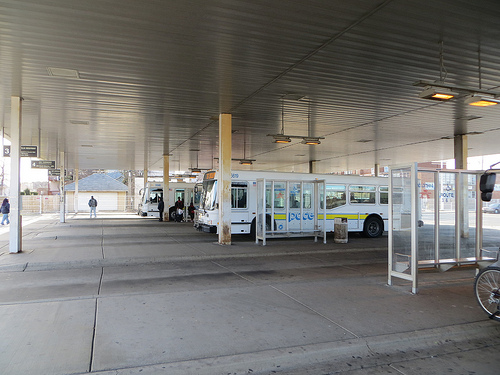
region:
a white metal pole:
[12, 99, 25, 260]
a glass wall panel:
[387, 164, 474, 292]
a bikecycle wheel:
[475, 266, 499, 320]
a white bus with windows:
[204, 172, 420, 230]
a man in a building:
[87, 197, 99, 220]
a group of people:
[157, 186, 194, 225]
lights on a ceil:
[268, 129, 323, 150]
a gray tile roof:
[67, 171, 129, 198]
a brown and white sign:
[30, 157, 55, 171]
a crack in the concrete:
[80, 243, 115, 355]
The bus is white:
[191, 170, 422, 237]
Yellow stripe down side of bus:
[257, 204, 382, 222]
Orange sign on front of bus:
[200, 170, 219, 184]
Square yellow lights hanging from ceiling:
[160, 92, 492, 184]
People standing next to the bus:
[149, 187, 193, 223]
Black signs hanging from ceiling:
[3, 142, 63, 181]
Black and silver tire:
[471, 265, 497, 323]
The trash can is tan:
[332, 216, 353, 246]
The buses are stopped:
[134, 162, 429, 252]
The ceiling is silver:
[1, 4, 495, 174]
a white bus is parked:
[165, 147, 453, 258]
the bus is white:
[189, 158, 418, 280]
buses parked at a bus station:
[139, 178, 424, 240]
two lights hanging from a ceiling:
[269, 81, 324, 149]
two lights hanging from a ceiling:
[423, 34, 498, 111]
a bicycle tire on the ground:
[471, 265, 497, 321]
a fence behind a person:
[4, 193, 139, 210]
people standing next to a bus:
[153, 193, 188, 223]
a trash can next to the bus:
[333, 217, 349, 241]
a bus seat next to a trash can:
[252, 176, 352, 246]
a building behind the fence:
[61, 172, 123, 213]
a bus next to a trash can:
[200, 173, 415, 241]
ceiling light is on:
[428, 92, 460, 102]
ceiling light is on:
[467, 98, 498, 108]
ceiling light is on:
[278, 139, 292, 142]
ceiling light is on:
[303, 138, 318, 143]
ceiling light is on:
[240, 157, 250, 162]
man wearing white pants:
[86, 191, 96, 213]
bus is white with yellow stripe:
[195, 170, 425, 236]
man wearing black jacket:
[0, 190, 8, 230]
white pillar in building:
[10, 98, 20, 253]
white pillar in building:
[57, 151, 66, 226]